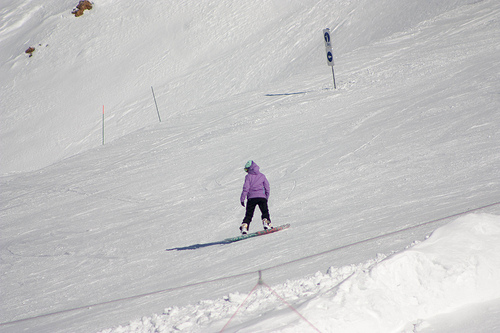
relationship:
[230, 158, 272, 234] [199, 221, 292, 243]
person riding snowboard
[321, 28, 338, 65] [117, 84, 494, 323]
sign in snow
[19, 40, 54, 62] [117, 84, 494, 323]
rocks in snow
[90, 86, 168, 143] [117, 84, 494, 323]
poles in snow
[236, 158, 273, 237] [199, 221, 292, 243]
person riding snowboard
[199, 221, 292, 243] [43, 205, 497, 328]
snowboard on ground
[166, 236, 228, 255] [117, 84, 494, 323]
shadow on top of snow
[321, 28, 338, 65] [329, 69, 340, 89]
sign attached to pole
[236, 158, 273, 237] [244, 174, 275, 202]
person wearing jacket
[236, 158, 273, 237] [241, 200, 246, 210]
person wearing glove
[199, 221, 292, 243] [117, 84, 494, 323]
snowboard on top of snow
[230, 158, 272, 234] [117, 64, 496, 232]
person on hill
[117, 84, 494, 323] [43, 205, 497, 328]
snow on ground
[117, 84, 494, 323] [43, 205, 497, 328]
snow covering ground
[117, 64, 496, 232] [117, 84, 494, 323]
hill covered with snow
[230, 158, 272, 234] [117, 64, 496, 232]
person skiing on hill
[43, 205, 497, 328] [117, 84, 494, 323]
ground covered with snow